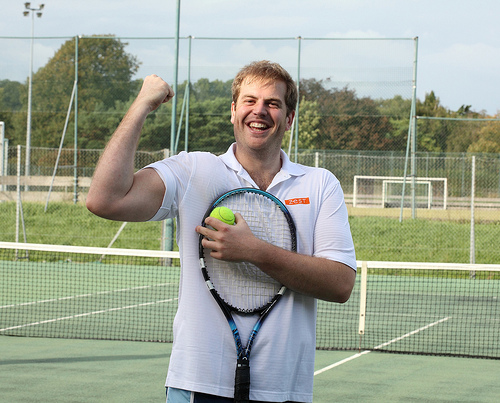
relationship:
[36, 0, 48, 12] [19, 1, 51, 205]
light on pole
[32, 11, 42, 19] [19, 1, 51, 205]
light on pole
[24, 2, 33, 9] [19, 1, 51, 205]
light on pole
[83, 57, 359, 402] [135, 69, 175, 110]
man makes fist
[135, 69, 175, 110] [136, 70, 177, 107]
fist on right hand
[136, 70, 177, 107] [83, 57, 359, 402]
right hand of man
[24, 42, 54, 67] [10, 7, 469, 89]
clouds in sky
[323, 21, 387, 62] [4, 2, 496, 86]
clouds in sky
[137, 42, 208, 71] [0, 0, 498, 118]
clouds in blue sky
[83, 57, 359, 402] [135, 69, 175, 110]
man making fist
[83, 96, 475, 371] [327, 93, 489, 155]
field surrounded by forest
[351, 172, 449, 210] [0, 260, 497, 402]
goal behind court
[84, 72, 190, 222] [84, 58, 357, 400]
arm of player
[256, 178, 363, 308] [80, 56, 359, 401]
arm of tennis player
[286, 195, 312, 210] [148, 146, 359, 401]
logo on shirt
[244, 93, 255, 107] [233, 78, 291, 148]
eye on face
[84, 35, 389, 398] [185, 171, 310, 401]
man holding racket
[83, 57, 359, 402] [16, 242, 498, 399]
man on tennis court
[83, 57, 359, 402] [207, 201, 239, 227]
man holding tennis ball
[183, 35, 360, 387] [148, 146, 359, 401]
man wearing shirt